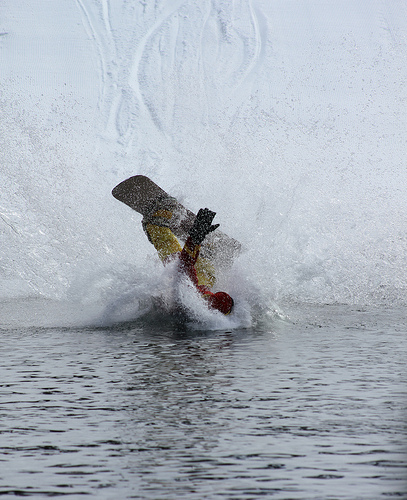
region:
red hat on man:
[199, 272, 251, 320]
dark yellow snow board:
[107, 165, 255, 263]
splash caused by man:
[20, 102, 336, 309]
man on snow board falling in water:
[96, 165, 292, 361]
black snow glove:
[181, 197, 231, 264]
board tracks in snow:
[74, 15, 228, 168]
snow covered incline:
[20, 18, 330, 204]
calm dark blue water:
[46, 367, 333, 485]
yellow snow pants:
[145, 224, 192, 255]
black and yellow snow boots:
[151, 195, 191, 242]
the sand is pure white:
[226, 119, 277, 156]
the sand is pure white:
[268, 168, 330, 174]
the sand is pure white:
[265, 103, 330, 158]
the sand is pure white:
[269, 123, 299, 156]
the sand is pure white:
[234, 31, 279, 79]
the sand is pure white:
[222, 72, 288, 134]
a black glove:
[185, 201, 228, 248]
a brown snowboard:
[110, 168, 254, 267]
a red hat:
[203, 286, 239, 322]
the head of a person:
[207, 277, 243, 319]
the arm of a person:
[172, 235, 206, 305]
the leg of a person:
[142, 215, 186, 272]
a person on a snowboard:
[111, 169, 256, 323]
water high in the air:
[76, 3, 291, 154]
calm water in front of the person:
[4, 328, 406, 498]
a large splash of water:
[107, 166, 264, 326]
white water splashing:
[86, 268, 227, 337]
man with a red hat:
[189, 281, 239, 331]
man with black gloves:
[173, 201, 245, 266]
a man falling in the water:
[99, 161, 267, 348]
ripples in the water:
[82, 345, 327, 482]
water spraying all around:
[30, 123, 377, 336]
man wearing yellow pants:
[139, 217, 247, 297]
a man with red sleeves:
[131, 198, 239, 302]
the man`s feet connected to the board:
[108, 168, 234, 268]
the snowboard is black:
[99, 162, 267, 307]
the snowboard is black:
[109, 124, 204, 258]